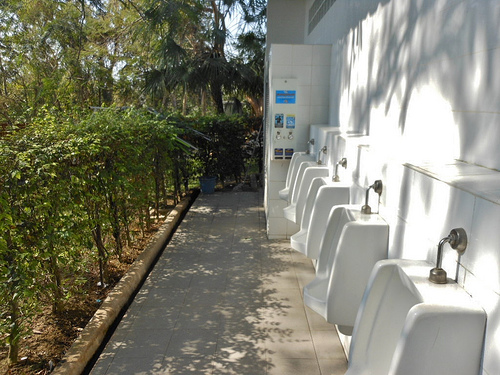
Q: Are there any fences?
A: No, there are no fences.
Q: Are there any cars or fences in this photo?
A: No, there are no fences or cars.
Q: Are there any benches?
A: No, there are no benches.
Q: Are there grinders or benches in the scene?
A: No, there are no benches or grinders.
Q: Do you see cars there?
A: No, there are no cars.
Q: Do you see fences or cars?
A: No, there are no cars or fences.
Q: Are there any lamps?
A: No, there are no lamps.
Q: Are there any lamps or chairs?
A: No, there are no lamps or chairs.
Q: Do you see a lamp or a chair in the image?
A: No, there are no lamps or chairs.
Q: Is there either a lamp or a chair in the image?
A: No, there are no lamps or chairs.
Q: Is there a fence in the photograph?
A: No, there are no fences.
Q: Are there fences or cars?
A: No, there are no fences or cars.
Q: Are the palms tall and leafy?
A: Yes, the palms are tall and leafy.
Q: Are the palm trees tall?
A: Yes, the palm trees are tall.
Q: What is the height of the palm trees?
A: The palm trees are tall.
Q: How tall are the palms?
A: The palms are tall.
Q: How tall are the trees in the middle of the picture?
A: The palms are tall.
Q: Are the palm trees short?
A: No, the palm trees are tall.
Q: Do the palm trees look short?
A: No, the palm trees are tall.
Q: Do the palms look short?
A: No, the palms are tall.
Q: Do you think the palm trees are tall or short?
A: The palm trees are tall.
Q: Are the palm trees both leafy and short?
A: No, the palm trees are leafy but tall.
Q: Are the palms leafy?
A: Yes, the palms are leafy.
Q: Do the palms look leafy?
A: Yes, the palms are leafy.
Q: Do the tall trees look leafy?
A: Yes, the palms are leafy.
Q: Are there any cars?
A: No, there are no cars.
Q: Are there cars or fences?
A: No, there are no cars or fences.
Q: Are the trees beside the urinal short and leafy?
A: Yes, the trees are short and leafy.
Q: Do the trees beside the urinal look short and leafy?
A: Yes, the trees are short and leafy.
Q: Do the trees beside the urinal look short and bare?
A: No, the trees are short but leafy.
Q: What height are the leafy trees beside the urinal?
A: The trees are short.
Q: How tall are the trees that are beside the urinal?
A: The trees are short.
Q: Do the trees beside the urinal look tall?
A: No, the trees are short.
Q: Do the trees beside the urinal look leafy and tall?
A: No, the trees are leafy but short.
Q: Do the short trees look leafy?
A: Yes, the trees are leafy.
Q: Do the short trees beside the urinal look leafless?
A: No, the trees are leafy.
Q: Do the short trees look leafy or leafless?
A: The trees are leafy.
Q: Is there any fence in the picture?
A: No, there are no fences.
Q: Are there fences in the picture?
A: No, there are no fences.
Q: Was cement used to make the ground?
A: Yes, the ground is made of cement.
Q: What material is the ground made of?
A: The ground is made of cement.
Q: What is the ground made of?
A: The ground is made of concrete.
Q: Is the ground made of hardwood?
A: No, the ground is made of cement.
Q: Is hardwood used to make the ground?
A: No, the ground is made of cement.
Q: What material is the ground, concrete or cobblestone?
A: The ground is made of concrete.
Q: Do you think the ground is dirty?
A: Yes, the ground is dirty.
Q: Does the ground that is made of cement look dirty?
A: Yes, the ground is dirty.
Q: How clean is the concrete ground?
A: The ground is dirty.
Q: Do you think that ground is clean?
A: No, the ground is dirty.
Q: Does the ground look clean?
A: No, the ground is dirty.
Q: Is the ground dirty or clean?
A: The ground is dirty.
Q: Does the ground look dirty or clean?
A: The ground is dirty.